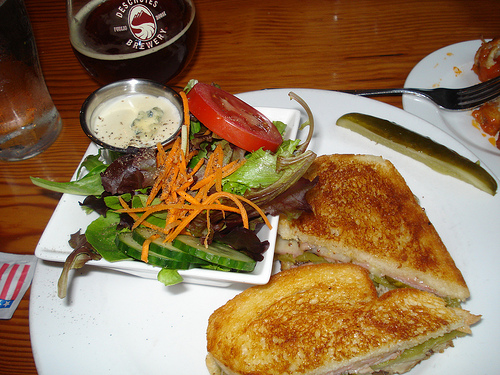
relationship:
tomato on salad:
[164, 71, 294, 171] [92, 80, 305, 308]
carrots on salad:
[119, 148, 221, 227] [59, 77, 300, 256]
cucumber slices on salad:
[115, 223, 256, 273] [44, 82, 307, 282]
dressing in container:
[104, 96, 166, 150] [85, 112, 170, 187]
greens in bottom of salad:
[66, 182, 153, 280] [37, 90, 379, 294]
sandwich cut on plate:
[249, 150, 474, 300] [28, 87, 498, 375]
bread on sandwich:
[289, 314, 363, 344] [213, 243, 476, 373]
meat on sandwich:
[365, 351, 416, 372] [215, 257, 471, 373]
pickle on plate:
[346, 111, 490, 192] [355, 115, 496, 299]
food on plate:
[89, 111, 404, 367] [28, 87, 498, 369]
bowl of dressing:
[75, 71, 195, 166] [90, 91, 166, 149]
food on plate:
[48, 83, 499, 374] [28, 87, 498, 369]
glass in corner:
[4, 4, 75, 174] [3, 2, 113, 177]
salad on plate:
[44, 82, 307, 282] [28, 87, 498, 369]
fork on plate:
[343, 77, 496, 112] [374, 24, 499, 183]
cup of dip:
[74, 79, 185, 154] [96, 100, 174, 141]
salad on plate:
[44, 82, 307, 282] [33, 105, 303, 289]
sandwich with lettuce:
[194, 143, 469, 373] [382, 335, 465, 370]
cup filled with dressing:
[74, 77, 190, 154] [103, 89, 170, 140]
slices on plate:
[124, 226, 258, 279] [33, 92, 312, 298]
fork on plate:
[343, 77, 496, 112] [399, 39, 499, 174]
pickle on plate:
[335, 111, 496, 192] [28, 87, 498, 369]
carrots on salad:
[112, 91, 273, 264] [26, 88, 318, 302]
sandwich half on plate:
[203, 260, 485, 370] [28, 87, 498, 369]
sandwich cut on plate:
[249, 150, 474, 300] [28, 87, 498, 369]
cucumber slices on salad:
[115, 223, 256, 273] [26, 88, 318, 302]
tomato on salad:
[188, 82, 284, 165] [26, 88, 318, 302]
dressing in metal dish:
[90, 91, 166, 149] [85, 76, 188, 166]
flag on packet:
[0, 257, 32, 311] [0, 251, 38, 322]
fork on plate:
[343, 77, 496, 112] [398, 38, 498, 186]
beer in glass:
[74, 5, 199, 89] [63, 0, 205, 91]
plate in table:
[28, 87, 498, 369] [0, 2, 500, 371]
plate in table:
[399, 39, 499, 174] [0, 2, 500, 371]